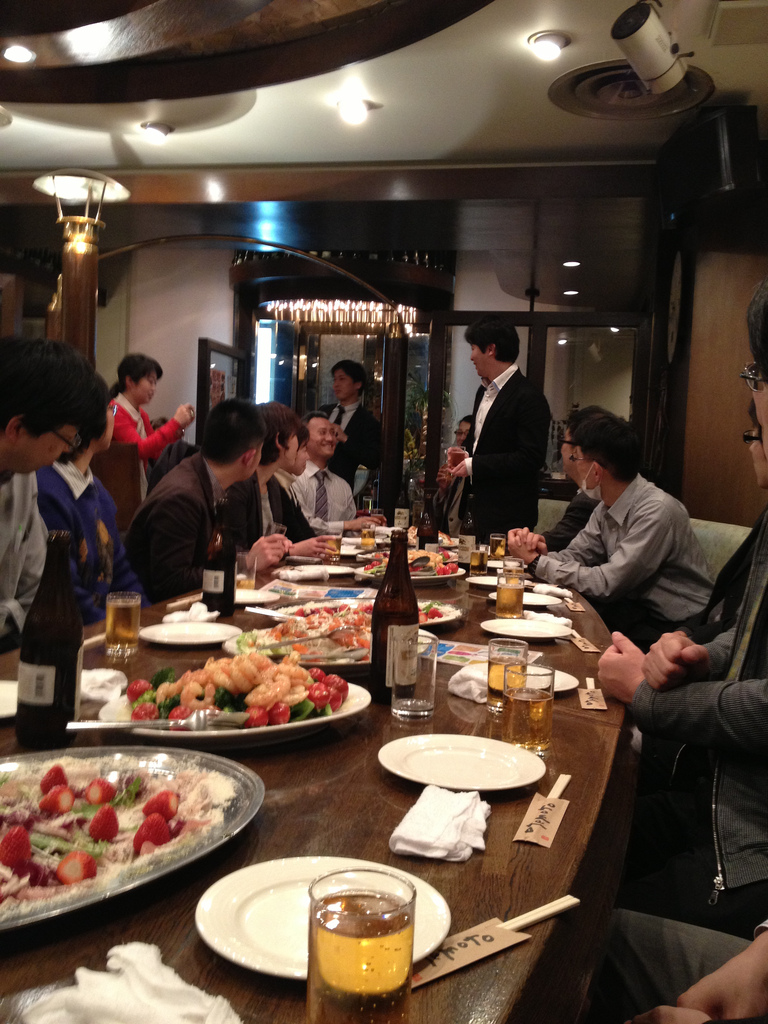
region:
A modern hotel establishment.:
[0, 1, 767, 1022]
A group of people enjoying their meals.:
[0, 288, 766, 1021]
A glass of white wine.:
[306, 869, 415, 1022]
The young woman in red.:
[109, 354, 192, 458]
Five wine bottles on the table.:
[11, 481, 436, 743]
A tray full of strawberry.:
[0, 741, 267, 928]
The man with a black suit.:
[446, 318, 552, 536]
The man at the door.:
[311, 357, 384, 506]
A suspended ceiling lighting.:
[37, 172, 125, 353]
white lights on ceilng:
[258, 20, 624, 147]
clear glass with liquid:
[289, 891, 420, 1020]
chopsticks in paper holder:
[370, 884, 580, 1000]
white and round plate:
[232, 827, 515, 974]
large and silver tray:
[2, 744, 258, 884]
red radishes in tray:
[8, 744, 205, 928]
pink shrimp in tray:
[94, 652, 315, 717]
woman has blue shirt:
[39, 450, 107, 643]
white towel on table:
[351, 737, 489, 912]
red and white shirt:
[127, 354, 166, 443]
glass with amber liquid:
[302, 881, 429, 1021]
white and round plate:
[166, 837, 420, 1003]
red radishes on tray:
[0, 754, 175, 916]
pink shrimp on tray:
[138, 604, 311, 742]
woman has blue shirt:
[17, 438, 133, 602]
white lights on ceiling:
[305, 43, 517, 163]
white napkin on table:
[375, 795, 495, 882]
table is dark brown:
[294, 743, 445, 863]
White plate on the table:
[190, 852, 452, 984]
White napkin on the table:
[379, 781, 496, 866]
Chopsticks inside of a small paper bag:
[545, 768, 573, 797]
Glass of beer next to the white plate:
[306, 868, 415, 1022]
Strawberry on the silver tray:
[128, 813, 171, 855]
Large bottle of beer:
[369, 527, 423, 703]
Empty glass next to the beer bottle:
[392, 630, 440, 722]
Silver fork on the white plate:
[60, 706, 239, 737]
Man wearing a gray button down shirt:
[504, 400, 716, 633]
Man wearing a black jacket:
[442, 315, 549, 530]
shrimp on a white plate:
[95, 640, 371, 744]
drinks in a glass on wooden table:
[475, 636, 607, 751]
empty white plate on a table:
[364, 723, 562, 812]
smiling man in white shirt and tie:
[290, 406, 366, 529]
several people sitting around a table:
[18, 330, 751, 720]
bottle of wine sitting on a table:
[357, 519, 438, 716]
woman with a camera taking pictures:
[99, 343, 205, 463]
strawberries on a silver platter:
[6, 760, 261, 847]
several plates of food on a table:
[114, 540, 485, 801]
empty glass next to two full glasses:
[372, 627, 580, 752]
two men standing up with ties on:
[303, 304, 567, 555]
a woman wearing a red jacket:
[89, 355, 209, 502]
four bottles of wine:
[9, 465, 443, 753]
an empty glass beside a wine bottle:
[364, 518, 448, 740]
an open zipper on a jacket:
[692, 724, 734, 907]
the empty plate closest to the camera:
[187, 846, 449, 986]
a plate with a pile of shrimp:
[99, 643, 375, 742]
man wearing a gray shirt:
[585, 480, 721, 607]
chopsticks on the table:
[503, 751, 596, 853]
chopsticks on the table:
[397, 875, 594, 998]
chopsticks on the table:
[557, 586, 585, 618]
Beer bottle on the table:
[357, 521, 439, 691]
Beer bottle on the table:
[8, 523, 103, 738]